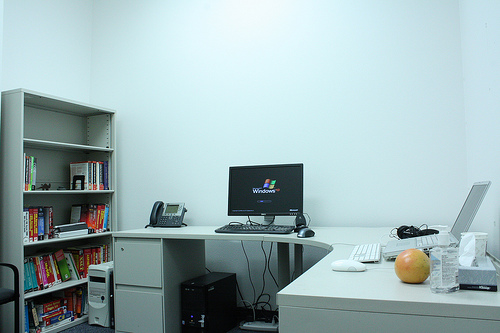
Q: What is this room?
A: Office.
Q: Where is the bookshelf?
A: In the corner.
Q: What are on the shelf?
A: Books.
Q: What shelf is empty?
A: Top shelf.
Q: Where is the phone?
A: On left side of the desk.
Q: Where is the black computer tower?
A: Under the desk.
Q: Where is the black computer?
A: Left side of the desk.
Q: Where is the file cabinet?
A: Under the left side of the desk.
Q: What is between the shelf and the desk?
A: White computer tower.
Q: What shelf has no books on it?
A: The top shelf.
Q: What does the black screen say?
A: Windows.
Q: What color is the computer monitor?
A: Black.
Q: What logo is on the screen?
A: Windows.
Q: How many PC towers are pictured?
A: Two.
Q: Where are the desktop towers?
A: On the floor.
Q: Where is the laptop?
A: On the desk.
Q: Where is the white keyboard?
A: Next to the laptop.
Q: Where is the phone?
A: Above the file cabinets.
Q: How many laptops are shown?
A: One.